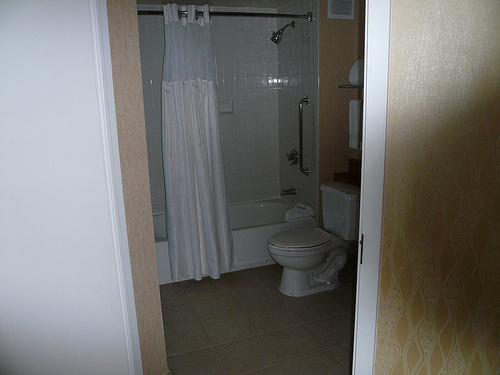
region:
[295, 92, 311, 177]
safety handle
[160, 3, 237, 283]
cloth and netting shower curtain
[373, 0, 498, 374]
gold print wall paper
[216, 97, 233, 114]
soap dish attached to shower wall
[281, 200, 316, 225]
towel folded into a triangle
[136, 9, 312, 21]
shower curtain rod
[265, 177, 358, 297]
porcelain toilet and tank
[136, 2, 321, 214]
white tiled shower back splash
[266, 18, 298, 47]
shower head fixture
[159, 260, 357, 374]
brown tiled flooring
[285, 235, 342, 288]
white toilet in a hotel bathroom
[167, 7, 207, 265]
white shower curtain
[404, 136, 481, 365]
beige and white patterned wallpaper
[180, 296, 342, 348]
stone tile floor in a hotel bathroom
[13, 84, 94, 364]
white wall to the left of the bathroom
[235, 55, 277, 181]
white tiled shower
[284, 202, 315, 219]
folded towel on the edge of the bathtub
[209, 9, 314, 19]
silver shower curtain rod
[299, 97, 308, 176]
silver handlebar attached to the shower wall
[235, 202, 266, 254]
white bathtub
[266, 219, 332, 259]
toilet lid is down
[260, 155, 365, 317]
white porcelain toilet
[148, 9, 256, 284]
white shower curtain that is pulled to one side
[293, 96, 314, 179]
metal bar in the shower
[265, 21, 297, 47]
silver showerhead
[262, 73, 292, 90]
light shining on the shower wall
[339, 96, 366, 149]
white hand towel hanging over a rod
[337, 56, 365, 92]
folded white towel on a shelf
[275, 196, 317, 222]
something white on the edge of the tub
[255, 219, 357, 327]
low white porcelain toilet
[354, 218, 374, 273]
small metal door latch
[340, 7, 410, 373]
white painted door trim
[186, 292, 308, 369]
tan stone tile flooring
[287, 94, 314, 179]
long metal safety rail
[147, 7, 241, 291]
long white shower curtain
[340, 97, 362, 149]
clean white hand towel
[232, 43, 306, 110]
clean white bath wall tile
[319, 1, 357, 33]
white metal heating vent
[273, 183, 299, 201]
silver metal tub faucet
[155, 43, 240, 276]
a long white shower curtain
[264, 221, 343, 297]
a porcelain toilet bowl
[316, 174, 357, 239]
a white toilet tank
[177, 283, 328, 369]
a light brown tile floor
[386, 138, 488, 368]
wavy designed wall paper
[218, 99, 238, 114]
a soap dish hanging on the shower wall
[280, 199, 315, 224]
a towel folded up on the side of the tub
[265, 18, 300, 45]
silver colored shower nozzle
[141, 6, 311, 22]
a shower curtain bar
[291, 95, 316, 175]
a safety grab bar in a shower